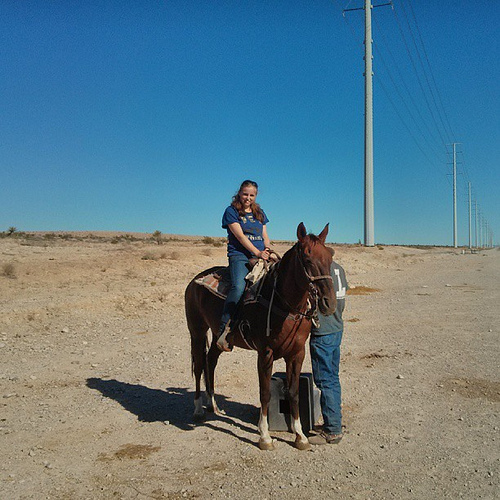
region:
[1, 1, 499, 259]
the sky is very bright and very blue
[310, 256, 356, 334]
the man is wearing a grey shirt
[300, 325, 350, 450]
the man is wearing blue jeans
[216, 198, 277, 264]
the girl has a t-shirt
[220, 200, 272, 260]
the girl's t-shirt is blue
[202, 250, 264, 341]
the girl is wearing jeans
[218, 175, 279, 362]
the girl is on a horse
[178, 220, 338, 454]
the horse is brown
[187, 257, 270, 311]
the blanket is on the horse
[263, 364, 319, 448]
the stool is next to the horse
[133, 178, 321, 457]
a horse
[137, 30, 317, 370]
a horse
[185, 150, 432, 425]
a horse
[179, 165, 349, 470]
a girl sits astride a horse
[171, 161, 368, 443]
the horse is a bay quarter horse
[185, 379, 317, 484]
the horse has 4 white stockings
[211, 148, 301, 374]
the girl does not appear to be an experienced rider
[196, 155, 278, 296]
she is wearing a blue tee shirt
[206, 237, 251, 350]
she is wearing a pair of jeans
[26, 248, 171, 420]
the land is very barren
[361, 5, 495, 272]
big posts are holding up the wires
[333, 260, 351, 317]
the number one is on the back of the man's shirt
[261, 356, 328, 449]
this is a step up to board the horse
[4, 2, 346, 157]
blue sky, no clouds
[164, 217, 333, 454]
chestnut horse with white feet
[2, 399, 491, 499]
dry stoney ground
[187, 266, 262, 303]
horse blanket under saddle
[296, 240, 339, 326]
the horse bridle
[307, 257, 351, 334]
back of army green t-shirt with number one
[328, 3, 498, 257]
a row of poles for utility lines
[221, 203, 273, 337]
blue jeand and blue shirt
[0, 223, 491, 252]
sparse vegetation along the horizon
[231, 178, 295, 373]
a girl rider holds the reins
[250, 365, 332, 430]
box used to get on horse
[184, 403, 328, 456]
horse has white on all his feet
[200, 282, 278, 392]
rider's foot in stirup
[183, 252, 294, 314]
blanket under the saddle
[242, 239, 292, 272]
woman holding the reins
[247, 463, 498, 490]
rocks in the dirt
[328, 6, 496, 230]
power lines are in the background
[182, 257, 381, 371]
color of the horse is brown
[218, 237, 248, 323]
woman is wearing jeans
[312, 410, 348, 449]
man is wearing cowboy boots